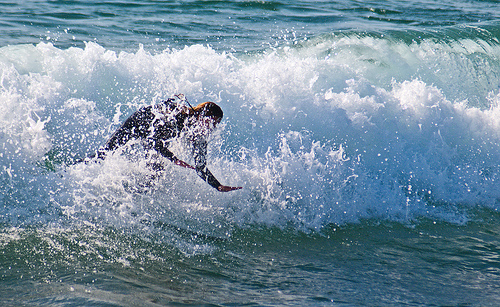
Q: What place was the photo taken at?
A: It was taken at the ocean.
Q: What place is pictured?
A: It is an ocean.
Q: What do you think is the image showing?
A: It is showing an ocean.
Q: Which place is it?
A: It is an ocean.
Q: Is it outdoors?
A: Yes, it is outdoors.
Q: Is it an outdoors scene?
A: Yes, it is outdoors.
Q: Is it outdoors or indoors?
A: It is outdoors.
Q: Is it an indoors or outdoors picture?
A: It is outdoors.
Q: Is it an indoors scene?
A: No, it is outdoors.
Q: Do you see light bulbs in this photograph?
A: No, there are no light bulbs.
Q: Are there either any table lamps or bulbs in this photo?
A: No, there are no bulbs or table lamps.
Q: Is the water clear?
A: Yes, the water is clear.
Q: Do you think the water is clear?
A: Yes, the water is clear.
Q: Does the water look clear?
A: Yes, the water is clear.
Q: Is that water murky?
A: No, the water is clear.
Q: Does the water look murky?
A: No, the water is clear.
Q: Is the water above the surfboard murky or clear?
A: The water is clear.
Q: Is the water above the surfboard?
A: Yes, the water is above the surfboard.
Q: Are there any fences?
A: No, there are no fences.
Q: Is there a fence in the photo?
A: No, there are no fences.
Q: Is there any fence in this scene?
A: No, there are no fences.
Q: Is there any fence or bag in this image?
A: No, there are no fences or bags.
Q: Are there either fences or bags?
A: No, there are no fences or bags.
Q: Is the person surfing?
A: Yes, the person is surfing.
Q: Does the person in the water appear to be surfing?
A: Yes, the person is surfing.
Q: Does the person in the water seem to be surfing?
A: Yes, the person is surfing.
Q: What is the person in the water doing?
A: The person is surfing.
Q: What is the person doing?
A: The person is surfing.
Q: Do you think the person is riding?
A: No, the person is surfing.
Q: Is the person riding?
A: No, the person is surfing.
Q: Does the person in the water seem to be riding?
A: No, the person is surfing.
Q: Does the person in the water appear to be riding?
A: No, the person is surfing.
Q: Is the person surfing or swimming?
A: The person is surfing.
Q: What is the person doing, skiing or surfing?
A: The person is surfing.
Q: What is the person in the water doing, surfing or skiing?
A: The person is surfing.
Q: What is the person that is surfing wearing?
A: The person is wearing a suit.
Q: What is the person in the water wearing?
A: The person is wearing a suit.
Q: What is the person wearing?
A: The person is wearing a suit.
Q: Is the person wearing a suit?
A: Yes, the person is wearing a suit.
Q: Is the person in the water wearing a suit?
A: Yes, the person is wearing a suit.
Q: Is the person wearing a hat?
A: No, the person is wearing a suit.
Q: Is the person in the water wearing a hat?
A: No, the person is wearing a suit.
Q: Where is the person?
A: The person is in the water.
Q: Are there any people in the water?
A: Yes, there is a person in the water.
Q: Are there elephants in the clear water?
A: No, there is a person in the water.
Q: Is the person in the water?
A: Yes, the person is in the water.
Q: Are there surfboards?
A: Yes, there is a surfboard.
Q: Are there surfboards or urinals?
A: Yes, there is a surfboard.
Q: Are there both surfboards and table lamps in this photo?
A: No, there is a surfboard but no table lamps.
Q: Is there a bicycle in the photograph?
A: No, there are no bicycles.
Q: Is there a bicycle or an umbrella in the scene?
A: No, there are no bicycles or umbrellas.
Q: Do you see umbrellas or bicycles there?
A: No, there are no bicycles or umbrellas.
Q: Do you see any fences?
A: No, there are no fences.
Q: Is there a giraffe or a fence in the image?
A: No, there are no fences or giraffes.